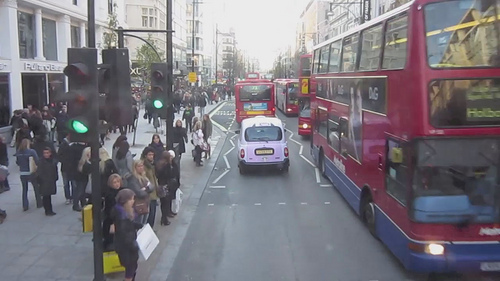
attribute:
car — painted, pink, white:
[233, 112, 293, 175]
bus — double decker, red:
[294, 50, 318, 138]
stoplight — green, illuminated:
[65, 114, 98, 140]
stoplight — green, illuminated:
[150, 95, 166, 112]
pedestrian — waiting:
[34, 145, 60, 218]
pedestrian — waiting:
[13, 136, 46, 213]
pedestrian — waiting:
[110, 187, 148, 280]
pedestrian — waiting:
[145, 129, 167, 163]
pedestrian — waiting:
[114, 136, 137, 191]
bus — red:
[227, 74, 280, 125]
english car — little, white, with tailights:
[234, 116, 291, 172]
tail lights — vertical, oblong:
[283, 146, 288, 155]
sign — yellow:
[185, 69, 197, 84]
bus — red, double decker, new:
[306, 2, 493, 270]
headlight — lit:
[426, 241, 445, 256]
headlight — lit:
[300, 121, 308, 128]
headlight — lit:
[287, 106, 292, 111]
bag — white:
[137, 217, 159, 259]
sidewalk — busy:
[0, 81, 232, 278]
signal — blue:
[64, 44, 99, 139]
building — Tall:
[1, 0, 123, 142]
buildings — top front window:
[441, 19, 498, 116]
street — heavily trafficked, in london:
[156, 82, 395, 279]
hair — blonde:
[116, 188, 133, 201]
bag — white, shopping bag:
[134, 219, 161, 259]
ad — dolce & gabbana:
[317, 74, 390, 107]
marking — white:
[210, 98, 239, 195]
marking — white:
[285, 122, 330, 188]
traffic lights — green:
[60, 41, 174, 143]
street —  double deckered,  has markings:
[186, 70, 328, 279]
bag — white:
[78, 173, 163, 273]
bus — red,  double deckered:
[201, 46, 296, 138]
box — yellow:
[76, 195, 100, 233]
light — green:
[148, 97, 165, 111]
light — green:
[64, 110, 94, 137]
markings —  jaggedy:
[216, 115, 319, 202]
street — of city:
[168, 98, 406, 279]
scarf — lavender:
[109, 204, 133, 219]